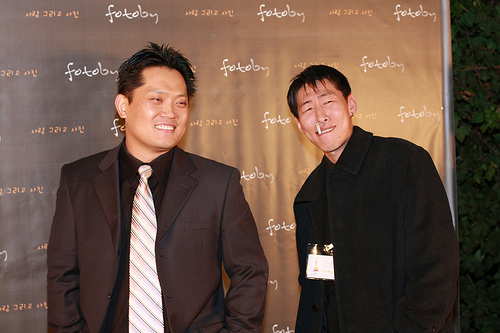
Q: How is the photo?
A: Clear.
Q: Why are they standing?
A: Posing for a photo.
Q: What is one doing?
A: Smoking.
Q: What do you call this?
A: Photo shoot.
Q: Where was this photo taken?
A: At a movie premiere.